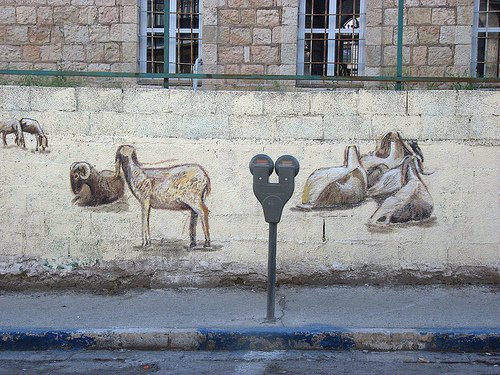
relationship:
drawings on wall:
[67, 136, 227, 254] [2, 64, 496, 281]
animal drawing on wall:
[115, 149, 214, 248] [1, 1, 499, 283]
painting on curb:
[198, 313, 333, 353] [1, 322, 498, 349]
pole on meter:
[261, 230, 281, 323] [244, 142, 305, 229]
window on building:
[141, 1, 203, 78] [0, 0, 498, 292]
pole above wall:
[2, 63, 491, 90] [120, 31, 480, 322]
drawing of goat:
[108, 118, 229, 253] [108, 128, 220, 257]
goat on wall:
[108, 128, 220, 257] [0, 83, 499, 284]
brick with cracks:
[22, 25, 51, 44] [126, 282, 252, 334]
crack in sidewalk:
[278, 284, 293, 335] [11, 279, 495, 370]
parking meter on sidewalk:
[248, 153, 298, 324] [1, 284, 498, 346]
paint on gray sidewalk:
[0, 322, 499, 356] [0, 283, 499, 333]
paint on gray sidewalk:
[5, 329, 85, 352] [0, 283, 499, 333]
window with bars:
[140, 0, 204, 86] [299, 4, 358, 76]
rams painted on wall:
[1, 119, 432, 251] [0, 83, 499, 284]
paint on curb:
[0, 322, 499, 356] [6, 325, 493, 348]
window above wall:
[295, 1, 362, 86] [12, 93, 495, 259]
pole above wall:
[396, 3, 407, 83] [12, 93, 495, 259]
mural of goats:
[0, 85, 499, 290] [289, 129, 437, 231]